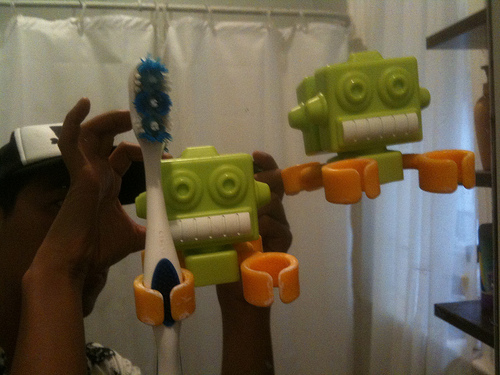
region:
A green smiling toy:
[130, 140, 321, 310]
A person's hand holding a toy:
[66, 88, 151, 268]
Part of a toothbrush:
[108, 128, 255, 348]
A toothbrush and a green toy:
[123, 150, 478, 336]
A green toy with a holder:
[78, 112, 353, 344]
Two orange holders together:
[101, 258, 395, 338]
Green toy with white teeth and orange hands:
[282, 43, 485, 215]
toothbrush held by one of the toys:
[123, 54, 188, 374]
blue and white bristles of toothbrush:
[126, 57, 174, 145]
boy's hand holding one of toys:
[31, 90, 171, 262]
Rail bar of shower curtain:
[1, 0, 363, 32]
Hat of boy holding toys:
[6, 120, 169, 207]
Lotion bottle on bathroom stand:
[472, 62, 492, 181]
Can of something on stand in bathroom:
[474, 210, 499, 317]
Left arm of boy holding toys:
[218, 146, 280, 373]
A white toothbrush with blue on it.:
[127, 56, 184, 373]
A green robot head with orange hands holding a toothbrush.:
[133, 145, 300, 328]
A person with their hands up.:
[0, 96, 292, 373]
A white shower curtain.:
[2, 2, 359, 372]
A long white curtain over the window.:
[349, 3, 485, 373]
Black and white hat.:
[0, 122, 142, 204]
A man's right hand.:
[36, 94, 173, 289]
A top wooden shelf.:
[424, 12, 490, 51]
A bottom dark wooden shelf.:
[435, 299, 496, 346]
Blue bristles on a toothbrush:
[132, 57, 171, 144]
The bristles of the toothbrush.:
[135, 59, 175, 147]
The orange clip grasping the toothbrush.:
[130, 268, 196, 324]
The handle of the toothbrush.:
[141, 152, 183, 374]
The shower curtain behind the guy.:
[0, 2, 355, 374]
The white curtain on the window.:
[349, 2, 478, 371]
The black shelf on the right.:
[432, 293, 499, 348]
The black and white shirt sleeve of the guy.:
[75, 343, 137, 374]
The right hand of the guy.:
[220, 147, 292, 309]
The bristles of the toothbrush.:
[131, 60, 172, 150]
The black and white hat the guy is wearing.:
[7, 116, 147, 186]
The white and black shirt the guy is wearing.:
[55, 330, 150, 370]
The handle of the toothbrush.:
[138, 138, 184, 371]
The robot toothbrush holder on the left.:
[139, 146, 290, 318]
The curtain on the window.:
[353, 6, 483, 373]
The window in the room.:
[389, 5, 487, 335]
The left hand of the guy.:
[62, 96, 152, 263]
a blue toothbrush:
[125, 53, 192, 372]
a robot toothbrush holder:
[302, 43, 480, 208]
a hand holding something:
[11, 96, 154, 373]